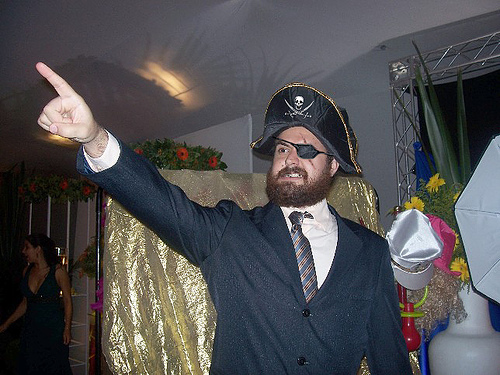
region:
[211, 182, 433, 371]
the man is wearing a suit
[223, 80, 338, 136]
the man has pirate wear on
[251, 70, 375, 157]
the man has a pirate hat on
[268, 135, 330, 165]
the man has an eye patch on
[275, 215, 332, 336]
the neck tie is striped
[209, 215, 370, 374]
the suit jacket is black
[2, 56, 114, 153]
the man is pointing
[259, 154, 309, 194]
the man has a beard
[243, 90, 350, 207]
head of a person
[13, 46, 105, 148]
hand of a person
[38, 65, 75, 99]
index finger of a person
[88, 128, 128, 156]
wrist of a person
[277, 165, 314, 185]
mouth of a person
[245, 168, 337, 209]
beard of a person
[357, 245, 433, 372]
arm of a person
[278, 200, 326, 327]
tie of a person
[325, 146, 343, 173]
ear of a person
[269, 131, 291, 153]
eye of a person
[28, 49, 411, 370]
This is a person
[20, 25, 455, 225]
A person is pointing in the air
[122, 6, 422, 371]
A person is wearing a pirate hat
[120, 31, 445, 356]
A person is wearing a beard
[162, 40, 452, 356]
A person is wearing an eye patch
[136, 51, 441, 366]
A person is wearing a blue jacket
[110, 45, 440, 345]
A person is wearing a necktie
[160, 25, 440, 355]
The person is inside the house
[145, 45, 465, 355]
A person is inside a room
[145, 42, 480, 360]
The person is having good fun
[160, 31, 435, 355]
A person is enjoying the day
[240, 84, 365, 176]
A hat in the photo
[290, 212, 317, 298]
A tie in the photo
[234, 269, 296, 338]
A blazer in the photo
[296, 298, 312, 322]
Button on the blazer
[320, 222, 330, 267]
White shirt in the photo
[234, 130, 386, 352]
A man in the room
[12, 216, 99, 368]
A woman in the room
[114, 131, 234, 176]
Floral decorations in the room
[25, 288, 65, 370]
A blue dress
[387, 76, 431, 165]
Metal stand in the room